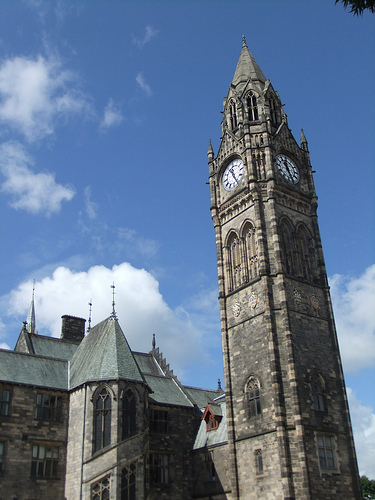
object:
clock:
[220, 157, 245, 191]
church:
[0, 277, 154, 500]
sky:
[0, 0, 374, 485]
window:
[224, 217, 258, 293]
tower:
[205, 34, 362, 498]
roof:
[68, 313, 154, 391]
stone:
[63, 402, 94, 484]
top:
[218, 33, 287, 131]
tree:
[333, 0, 374, 18]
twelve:
[224, 157, 243, 168]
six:
[226, 177, 239, 193]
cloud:
[133, 67, 155, 95]